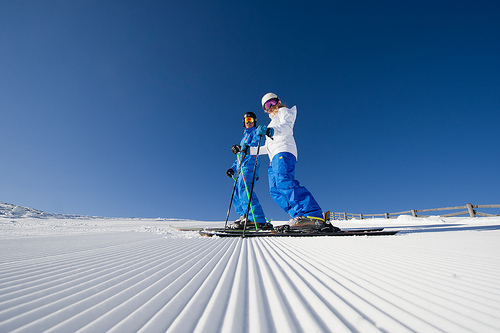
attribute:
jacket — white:
[248, 105, 299, 164]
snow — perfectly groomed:
[120, 268, 207, 321]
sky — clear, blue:
[350, 24, 447, 98]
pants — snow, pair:
[265, 153, 318, 219]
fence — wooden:
[397, 205, 481, 226]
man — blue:
[222, 110, 267, 228]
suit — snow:
[229, 123, 269, 224]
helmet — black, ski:
[240, 111, 256, 129]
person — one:
[240, 92, 326, 232]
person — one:
[225, 110, 265, 231]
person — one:
[243, 88, 330, 227]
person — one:
[227, 112, 270, 227]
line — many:
[176, 275, 207, 329]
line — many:
[193, 276, 222, 330]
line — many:
[267, 286, 290, 330]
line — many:
[48, 286, 90, 331]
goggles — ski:
[262, 100, 282, 113]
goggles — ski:
[242, 115, 257, 129]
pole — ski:
[245, 139, 265, 231]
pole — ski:
[223, 152, 245, 232]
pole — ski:
[236, 148, 258, 232]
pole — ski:
[231, 169, 235, 187]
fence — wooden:
[338, 204, 481, 219]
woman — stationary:
[237, 91, 328, 225]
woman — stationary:
[226, 113, 267, 228]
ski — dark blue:
[7, 19, 193, 119]